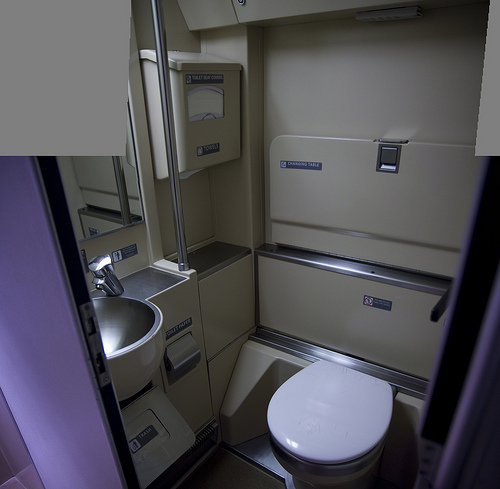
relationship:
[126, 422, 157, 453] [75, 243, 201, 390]
sign under sink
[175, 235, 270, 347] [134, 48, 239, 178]
trash can under towel dispenser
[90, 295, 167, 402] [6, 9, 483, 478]
sink in bathroom